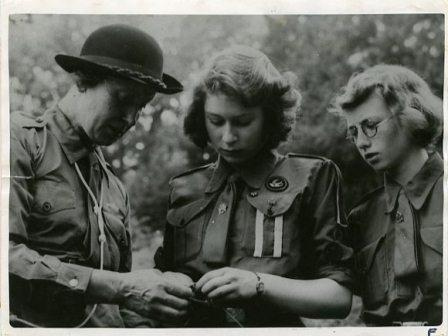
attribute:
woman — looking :
[142, 62, 350, 330]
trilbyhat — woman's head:
[41, 21, 196, 101]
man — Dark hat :
[14, 17, 180, 311]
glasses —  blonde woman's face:
[338, 108, 390, 148]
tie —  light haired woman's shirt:
[199, 184, 240, 258]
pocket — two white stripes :
[169, 197, 305, 264]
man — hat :
[15, 20, 199, 306]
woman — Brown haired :
[149, 30, 359, 330]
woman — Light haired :
[129, 42, 348, 328]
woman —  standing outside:
[122, 44, 357, 304]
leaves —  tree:
[318, 50, 391, 73]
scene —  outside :
[20, 26, 433, 320]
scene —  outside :
[20, 15, 410, 334]